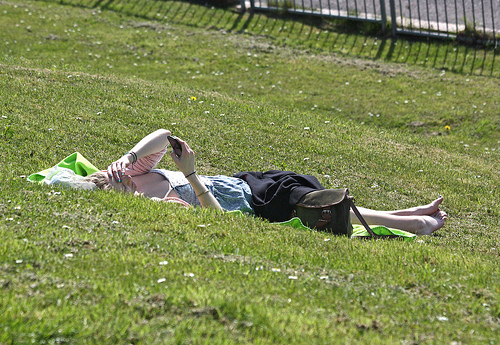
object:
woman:
[40, 128, 449, 235]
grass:
[3, 0, 498, 343]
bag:
[290, 186, 381, 238]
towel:
[26, 151, 419, 238]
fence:
[245, 0, 498, 80]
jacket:
[233, 170, 325, 223]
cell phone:
[166, 135, 182, 157]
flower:
[303, 126, 310, 131]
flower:
[96, 111, 103, 116]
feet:
[413, 210, 448, 234]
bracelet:
[196, 190, 211, 197]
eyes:
[116, 170, 127, 192]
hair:
[46, 167, 116, 191]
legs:
[351, 206, 448, 235]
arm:
[183, 170, 222, 209]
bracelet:
[185, 171, 196, 178]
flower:
[189, 95, 197, 101]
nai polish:
[116, 179, 120, 183]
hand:
[106, 153, 131, 183]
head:
[86, 170, 137, 195]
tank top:
[146, 168, 253, 215]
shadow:
[56, 0, 499, 79]